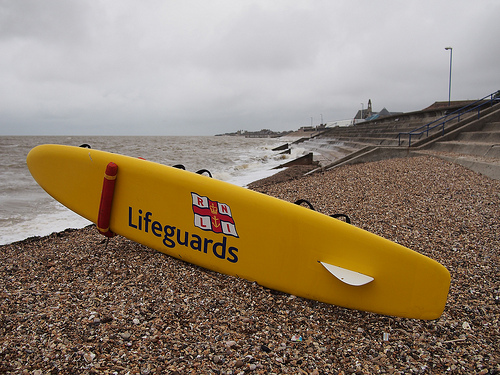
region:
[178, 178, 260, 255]
decorative flag on a yellow surf board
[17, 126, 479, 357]
yellow surf board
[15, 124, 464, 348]
Yellow surf board sitting on a rocky beach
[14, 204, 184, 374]
Rocky beach surface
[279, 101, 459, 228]
Concrete stairs leading down into the ocean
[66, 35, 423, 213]
Very overcast and cloudy day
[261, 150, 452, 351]
fin on the back of a yellow surf board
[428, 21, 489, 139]
light pole on the top of the cement stairs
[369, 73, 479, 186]
blue stair railings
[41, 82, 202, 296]
red surf board stand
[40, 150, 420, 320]
yellow and red surfboard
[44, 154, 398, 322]
yellow and red lifeguard surfboard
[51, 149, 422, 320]
yellow and red surfboard on beach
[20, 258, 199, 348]
white and brown pebbles on beach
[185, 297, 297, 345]
white and brown pebbles on beach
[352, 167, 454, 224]
white and brown pebbles on beach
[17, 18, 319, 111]
gray and white clouds in sky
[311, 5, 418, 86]
gray and white clouds in sky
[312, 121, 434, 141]
brown staircase by beach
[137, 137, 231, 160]
brown and white waves in ocean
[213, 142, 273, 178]
white waves crashing to shore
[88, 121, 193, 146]
rough brown waters in the bay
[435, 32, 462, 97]
large light pole on land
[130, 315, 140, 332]
small white pebble on sand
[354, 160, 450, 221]
brown stones on the sand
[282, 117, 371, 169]
steps leading up to the shore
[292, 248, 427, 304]
white fin on yellow surf board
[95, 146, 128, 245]
red object on surf board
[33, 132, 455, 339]
large yellow surf board in sand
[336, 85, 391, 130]
large houses in the distance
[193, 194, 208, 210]
The capital R on the surfboard.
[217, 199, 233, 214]
The capital N on the surfboard.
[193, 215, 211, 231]
The capital L on the surfboard.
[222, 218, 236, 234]
The capital I on the surfboard.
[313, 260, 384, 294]
The white fin on the surfboard.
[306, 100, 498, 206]
The stairs leading to the top.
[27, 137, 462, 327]
The yellow surfboard in the picture.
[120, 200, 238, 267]
The word Lifeguards on the surfboard.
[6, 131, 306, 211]
The water that leads to the stairs.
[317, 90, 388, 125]
The buildings in the distance.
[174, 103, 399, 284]
A yellow board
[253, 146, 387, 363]
A yellow board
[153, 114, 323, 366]
A yellow board